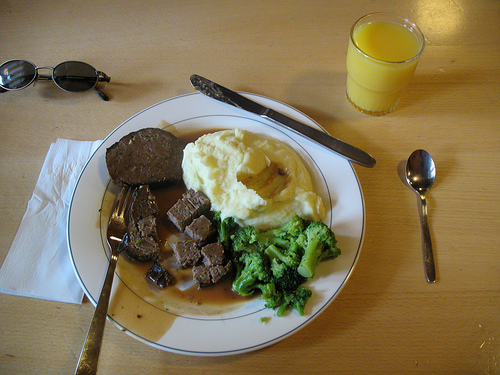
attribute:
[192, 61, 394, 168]
knife — resting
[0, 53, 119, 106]
sunglasses — black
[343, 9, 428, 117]
cup — filled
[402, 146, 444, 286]
spoon — silver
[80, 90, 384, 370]
plate — round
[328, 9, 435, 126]
cup — filled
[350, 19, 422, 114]
juice — orange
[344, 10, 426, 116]
glass — full, orange juice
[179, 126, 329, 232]
potatoes — piled, mashed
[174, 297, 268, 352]
plate — white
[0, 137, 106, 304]
napkin — white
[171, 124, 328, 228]
potatoes — mashed potatoes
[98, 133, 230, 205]
meatloaf — a large piece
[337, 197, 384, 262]
plate — white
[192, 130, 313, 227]
potato — mashed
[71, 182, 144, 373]
fork — resting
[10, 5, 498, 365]
table — wooden table, wooden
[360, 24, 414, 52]
juice — orange